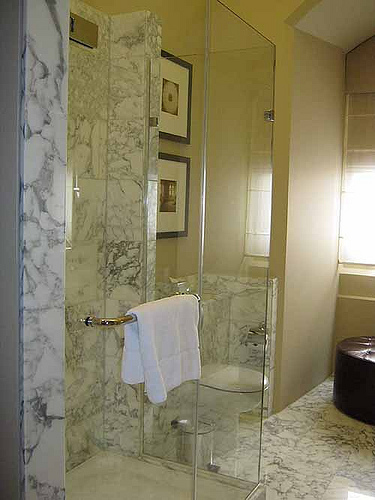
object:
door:
[149, 0, 276, 484]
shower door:
[63, 0, 207, 500]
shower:
[63, 1, 276, 500]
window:
[133, 211, 263, 482]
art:
[156, 49, 192, 240]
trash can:
[173, 418, 216, 471]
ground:
[298, 119, 326, 207]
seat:
[332, 335, 375, 427]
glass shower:
[76, 212, 269, 500]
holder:
[229, 318, 268, 347]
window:
[338, 90, 374, 265]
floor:
[150, 372, 371, 500]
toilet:
[192, 363, 268, 467]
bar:
[80, 291, 200, 326]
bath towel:
[121, 295, 202, 405]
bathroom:
[0, 2, 375, 499]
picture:
[156, 151, 191, 240]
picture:
[158, 48, 193, 145]